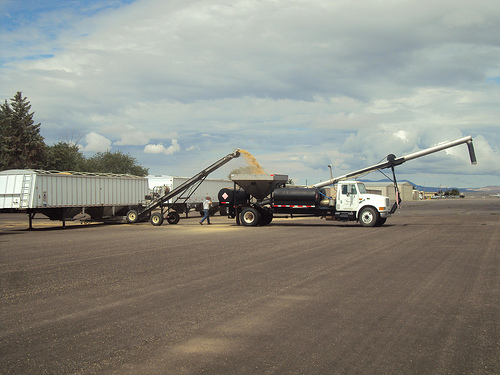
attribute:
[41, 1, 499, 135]
clouds — white, cloudy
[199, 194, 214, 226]
man — walking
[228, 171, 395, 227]
truck — steel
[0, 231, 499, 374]
roadside — asphalt, paved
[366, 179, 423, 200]
buildings — warehouses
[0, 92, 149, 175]
tree leaves — green